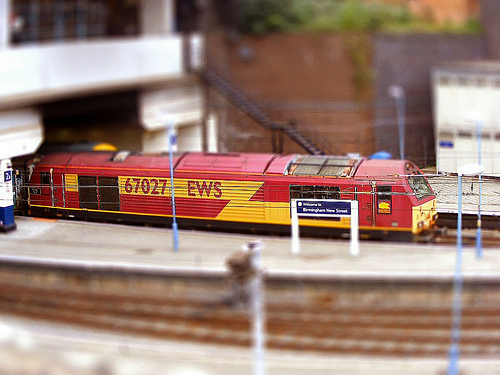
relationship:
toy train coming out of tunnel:
[15, 154, 438, 237] [25, 90, 144, 220]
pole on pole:
[163, 150, 184, 254] [443, 170, 470, 374]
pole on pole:
[389, 97, 414, 159] [443, 170, 470, 374]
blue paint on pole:
[447, 178, 466, 365] [443, 170, 470, 374]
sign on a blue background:
[296, 201, 350, 216] [292, 200, 352, 214]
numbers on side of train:
[120, 169, 172, 196] [25, 149, 438, 241]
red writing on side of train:
[121, 175, 225, 200] [12, 150, 439, 232]